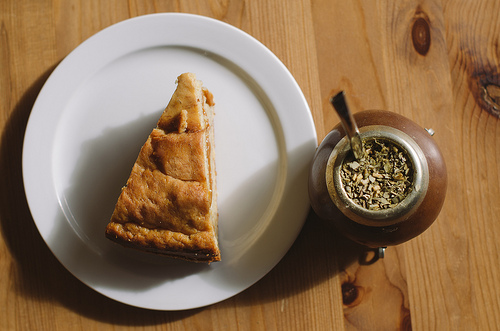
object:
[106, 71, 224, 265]
pie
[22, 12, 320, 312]
plate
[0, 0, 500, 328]
table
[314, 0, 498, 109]
wood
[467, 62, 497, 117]
knots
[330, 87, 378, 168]
spoon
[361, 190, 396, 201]
seeds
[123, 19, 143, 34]
rim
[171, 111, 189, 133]
crumb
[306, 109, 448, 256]
bowl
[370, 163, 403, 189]
oats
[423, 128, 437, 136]
silver handle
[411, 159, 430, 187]
silver rim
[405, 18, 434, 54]
spot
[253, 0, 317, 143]
stripes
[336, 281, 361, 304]
oval marking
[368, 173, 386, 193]
seasoning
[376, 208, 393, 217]
metal